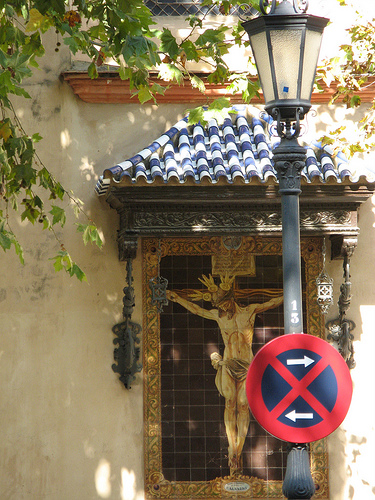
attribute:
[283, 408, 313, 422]
white arrow —  white,  pointing left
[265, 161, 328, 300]
pole — lamp's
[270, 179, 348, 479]
pole — gray, metal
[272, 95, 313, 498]
post — grey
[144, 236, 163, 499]
trimming — gold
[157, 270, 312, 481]
statue — building's 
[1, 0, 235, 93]
leaves — green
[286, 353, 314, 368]
arrow —  white,  pointing  right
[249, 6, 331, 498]
street lamp — decorative, metal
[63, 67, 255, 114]
board —  fresher,   building's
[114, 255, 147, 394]
fixture — gray, metal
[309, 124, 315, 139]
reflection — light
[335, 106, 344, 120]
reflection — light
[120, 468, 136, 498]
reflection — light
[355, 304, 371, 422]
reflection — light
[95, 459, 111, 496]
reflection — light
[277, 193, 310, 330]
pole — grey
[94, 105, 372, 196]
awning — blue, white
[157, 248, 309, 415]
painting — jesus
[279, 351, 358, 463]
sign — red and blue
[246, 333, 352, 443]
sign — circular, red, white, blue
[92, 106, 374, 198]
roof — grey, white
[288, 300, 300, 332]
numbers — white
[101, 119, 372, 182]
tiles — colored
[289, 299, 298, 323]
number — 13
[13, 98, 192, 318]
spots — light